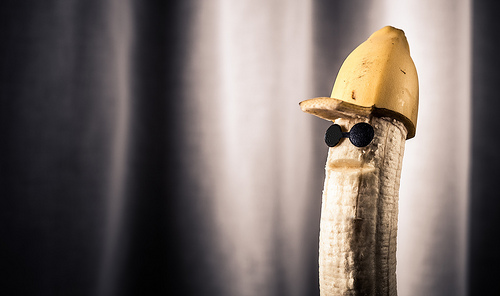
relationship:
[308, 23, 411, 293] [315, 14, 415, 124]
banana wearing hat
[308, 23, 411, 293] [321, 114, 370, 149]
banana wearing glasses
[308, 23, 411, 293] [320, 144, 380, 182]
banana has smile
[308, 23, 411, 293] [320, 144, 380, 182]
banana has mouth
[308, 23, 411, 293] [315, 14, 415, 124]
banana wearing cap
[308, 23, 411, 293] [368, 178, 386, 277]
banana has line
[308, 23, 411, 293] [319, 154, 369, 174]
banana has open mouth